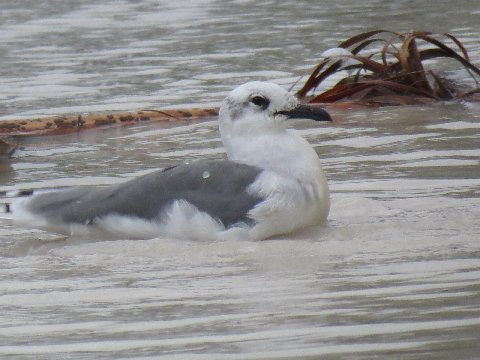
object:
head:
[215, 81, 334, 140]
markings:
[224, 94, 251, 122]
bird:
[8, 80, 333, 241]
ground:
[417, 151, 447, 190]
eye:
[247, 95, 269, 107]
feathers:
[11, 160, 303, 240]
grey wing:
[32, 161, 255, 230]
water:
[0, 0, 478, 360]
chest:
[274, 136, 326, 195]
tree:
[1, 103, 212, 139]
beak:
[275, 106, 334, 123]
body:
[5, 161, 331, 244]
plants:
[292, 28, 480, 107]